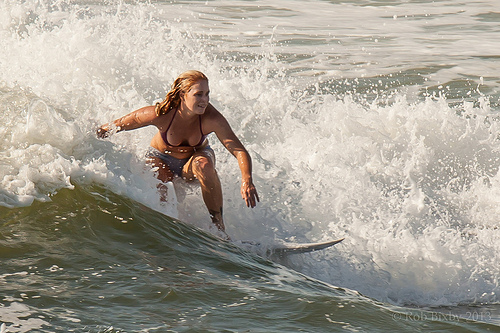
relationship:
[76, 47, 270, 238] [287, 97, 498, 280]
surfer in ocean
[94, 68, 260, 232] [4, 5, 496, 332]
surfer surfing in ocean